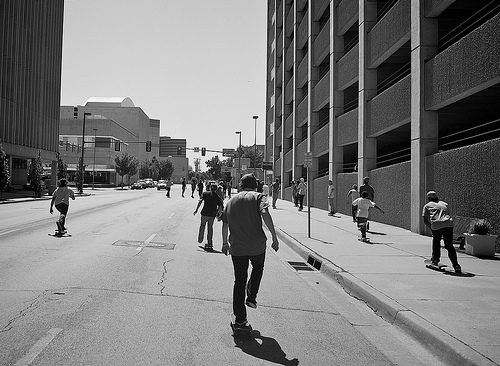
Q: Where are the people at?
A: Downtown.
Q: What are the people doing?
A: Skateboarding.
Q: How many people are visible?
A: Seventeen.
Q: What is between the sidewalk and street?
A: Drain.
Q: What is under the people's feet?
A: Skateboards.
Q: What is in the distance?
A: Buildings.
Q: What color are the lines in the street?
A: White.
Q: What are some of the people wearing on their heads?
A: Hats.